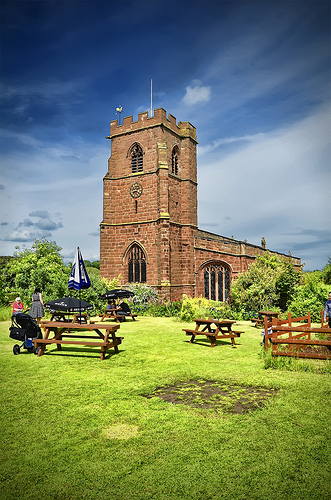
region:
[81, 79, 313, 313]
Brick building with different colored bricks.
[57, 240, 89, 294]
Umbrella folded, blue and gray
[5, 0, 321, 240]
Dark blue sky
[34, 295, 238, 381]
Light brown picnic tables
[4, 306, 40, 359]
Stroller next to picnic table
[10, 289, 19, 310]
Elderly woman sitting wearing sunglasses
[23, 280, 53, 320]
Young woman standing up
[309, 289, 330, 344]
Man standing on the edge looking to the left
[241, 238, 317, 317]
Bright green bushes and shrubs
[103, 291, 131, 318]
People sitting at a table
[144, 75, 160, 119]
flagpole on a roof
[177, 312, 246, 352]
picnic table on the grass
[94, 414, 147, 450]
a round spot in the grass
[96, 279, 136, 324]
a table with an umbrella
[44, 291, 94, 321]
a low umbrella over a table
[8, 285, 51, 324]
two ladies outside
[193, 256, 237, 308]
a window with an arch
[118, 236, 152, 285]
a decorative window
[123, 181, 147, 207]
clock face on a tower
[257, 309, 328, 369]
wooden fence with three rails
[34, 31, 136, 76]
dark skies overhead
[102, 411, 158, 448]
white circular spot in green grass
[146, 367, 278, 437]
square dirt patch on grass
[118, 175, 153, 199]
large brown clock on building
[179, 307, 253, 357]
large brown wooden bench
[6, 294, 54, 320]
woman wearing red jacket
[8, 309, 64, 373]
blue baby buggy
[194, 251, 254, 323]
large circular windows in red brick building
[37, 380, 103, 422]
well manicured green grass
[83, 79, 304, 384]
large old red brick building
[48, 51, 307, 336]
a very attractive brick building.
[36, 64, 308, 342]
a really tall brick building.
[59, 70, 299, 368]
a large brown brick building.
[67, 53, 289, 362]
a castle-like brown brick building.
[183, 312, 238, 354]
a wooden picnic style bench.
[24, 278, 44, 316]
a lady in a gray dress.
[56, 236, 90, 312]
an umbrella for shade.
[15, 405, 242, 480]
green grass patch of field.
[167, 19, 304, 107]
beautiful blue sky with clouds.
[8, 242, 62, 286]
some really healthy green trees.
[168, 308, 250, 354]
Medium sized wooden picnic table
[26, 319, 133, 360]
Medium sized wooden picnic table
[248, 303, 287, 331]
Medium sized wooden picnic table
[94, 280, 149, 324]
People sitting under an umbrella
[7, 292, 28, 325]
Person with white hair and red shirt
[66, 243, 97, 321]
Blue and white umbrella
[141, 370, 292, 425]
Large muddy spot in the grass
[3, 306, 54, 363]
Black baby stroller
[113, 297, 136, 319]
Person wearing a black shirt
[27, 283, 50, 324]
Person wearing a grey dress